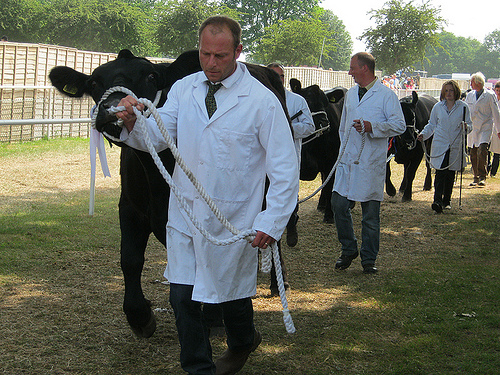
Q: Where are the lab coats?
A: On the workers.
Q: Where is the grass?
A: On the ground.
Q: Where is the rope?
A: In the man's hands.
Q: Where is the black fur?
A: On the cows.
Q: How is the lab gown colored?
A: White.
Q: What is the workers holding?
A: Ropes.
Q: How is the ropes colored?
A: White.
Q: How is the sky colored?
A: White.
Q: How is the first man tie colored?
A: Black.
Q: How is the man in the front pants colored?
A: Blue.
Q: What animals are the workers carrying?
A: Cows.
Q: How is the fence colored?
A: Tan.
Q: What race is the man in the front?
A: Caucasian.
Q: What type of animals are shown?
A: Cows.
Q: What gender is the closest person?
A: Male.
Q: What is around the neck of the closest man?
A: Tie.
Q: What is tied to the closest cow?
A: Rope.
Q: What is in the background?
A: Trees.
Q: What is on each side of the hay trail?
A: Grass.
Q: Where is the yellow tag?
A: Closest cow's ear.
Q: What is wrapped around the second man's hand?
A: Rope.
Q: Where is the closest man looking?
A: Down.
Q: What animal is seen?
A: Cow.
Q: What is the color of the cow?
A: Black.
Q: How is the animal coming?
A: In line.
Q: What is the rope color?
A: White.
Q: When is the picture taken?
A: Daytime.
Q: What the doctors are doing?
A: They are catching the cow rope.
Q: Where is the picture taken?
A: Near cows.